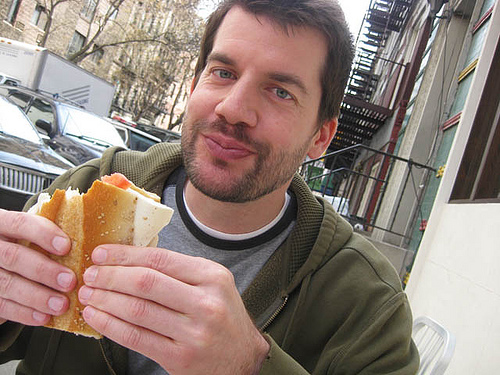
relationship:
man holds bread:
[0, 0, 422, 372] [14, 171, 174, 339]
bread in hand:
[14, 171, 174, 339] [88, 231, 268, 373]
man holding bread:
[0, 0, 422, 372] [14, 171, 174, 339]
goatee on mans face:
[179, 122, 311, 205] [180, 0, 354, 206]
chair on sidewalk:
[406, 314, 446, 372] [306, 209, 408, 371]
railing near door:
[306, 141, 442, 250] [398, 29, 493, 243]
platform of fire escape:
[326, 92, 391, 178] [322, 0, 419, 175]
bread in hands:
[97, 196, 133, 221] [0, 204, 263, 374]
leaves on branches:
[167, 22, 182, 37] [137, 30, 169, 58]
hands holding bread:
[0, 204, 263, 374] [14, 171, 174, 339]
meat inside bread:
[102, 171, 132, 190] [14, 171, 174, 339]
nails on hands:
[28, 225, 113, 339] [0, 204, 263, 374]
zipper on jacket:
[258, 288, 289, 332] [2, 134, 424, 374]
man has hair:
[0, 0, 422, 372] [193, 0, 359, 128]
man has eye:
[0, 0, 422, 372] [271, 85, 296, 104]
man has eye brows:
[16, 51, 430, 375] [205, 49, 310, 98]